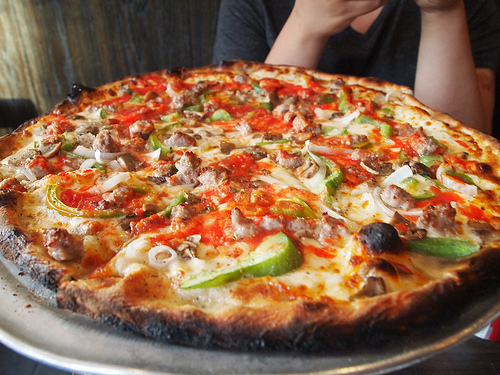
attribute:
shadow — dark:
[1, 95, 38, 130]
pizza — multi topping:
[2, 56, 499, 356]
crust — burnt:
[1, 220, 499, 353]